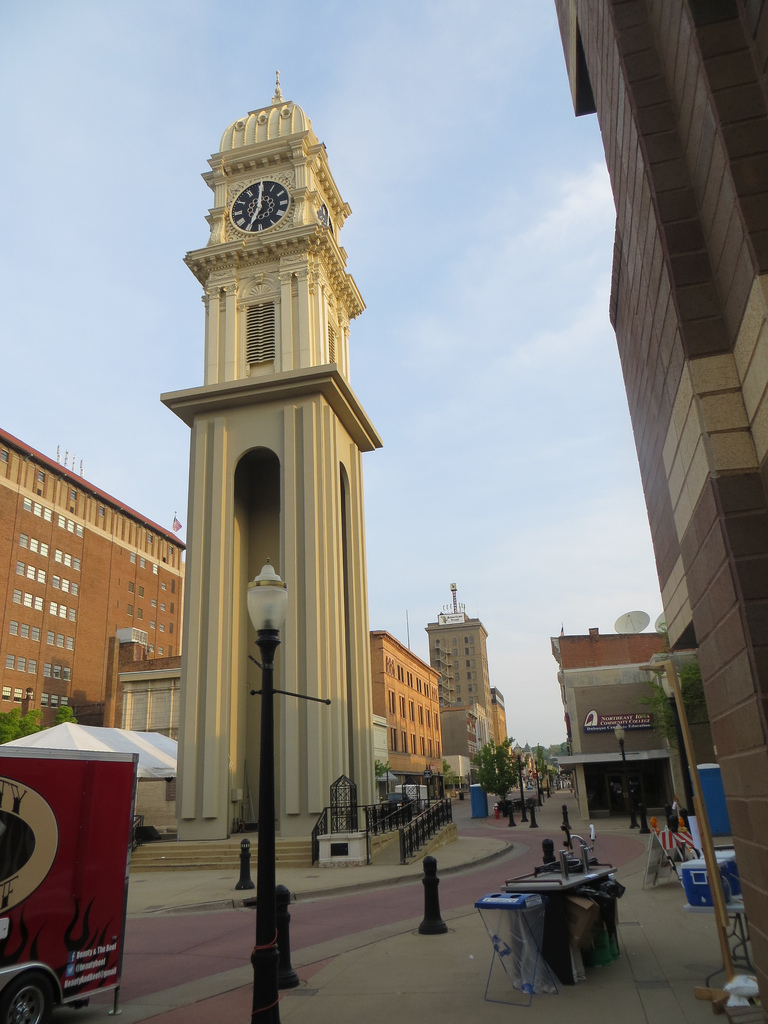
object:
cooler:
[681, 859, 733, 908]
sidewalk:
[269, 852, 759, 1021]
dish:
[614, 611, 649, 635]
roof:
[549, 629, 670, 673]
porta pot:
[469, 783, 488, 819]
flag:
[173, 517, 184, 533]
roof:
[0, 429, 186, 549]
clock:
[230, 180, 291, 234]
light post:
[248, 627, 331, 1022]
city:
[0, 0, 767, 1022]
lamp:
[246, 558, 290, 629]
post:
[256, 627, 282, 945]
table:
[684, 893, 756, 988]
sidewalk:
[136, 955, 336, 1023]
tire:
[0, 970, 59, 1020]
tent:
[0, 717, 178, 777]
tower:
[160, 69, 384, 839]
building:
[0, 430, 188, 728]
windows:
[0, 495, 85, 709]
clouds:
[502, 165, 617, 379]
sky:
[0, 0, 662, 747]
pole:
[253, 635, 283, 947]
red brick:
[123, 909, 257, 955]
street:
[123, 785, 768, 1023]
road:
[121, 785, 768, 1024]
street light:
[614, 723, 625, 742]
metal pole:
[419, 855, 449, 935]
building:
[424, 583, 496, 789]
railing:
[399, 799, 453, 867]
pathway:
[124, 789, 647, 1021]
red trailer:
[0, 745, 139, 1022]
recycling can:
[474, 893, 559, 1006]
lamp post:
[247, 558, 331, 1020]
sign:
[582, 707, 653, 732]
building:
[549, 610, 696, 823]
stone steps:
[128, 835, 317, 874]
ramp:
[367, 816, 458, 865]